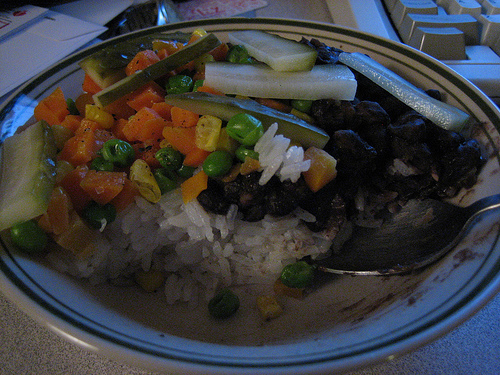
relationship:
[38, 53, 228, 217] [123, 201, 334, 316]
carrots on rice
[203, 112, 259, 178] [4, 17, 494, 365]
peas on dish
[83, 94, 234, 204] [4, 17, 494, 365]
corn on dish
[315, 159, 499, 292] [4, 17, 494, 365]
spoon on dish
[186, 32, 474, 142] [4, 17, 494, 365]
beans in dish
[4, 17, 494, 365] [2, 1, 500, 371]
dish on counter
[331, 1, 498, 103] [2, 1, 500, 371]
keyboard on counter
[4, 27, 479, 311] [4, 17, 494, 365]
food on dish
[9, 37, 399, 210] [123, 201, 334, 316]
vegetables on top of rice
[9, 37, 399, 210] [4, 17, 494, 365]
vegetables on dish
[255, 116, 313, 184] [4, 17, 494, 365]
rice on dish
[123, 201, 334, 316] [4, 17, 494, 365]
rice on dish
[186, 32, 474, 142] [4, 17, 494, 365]
beans on dish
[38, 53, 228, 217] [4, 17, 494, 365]
carrots on dish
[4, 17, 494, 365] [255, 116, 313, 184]
dish has rice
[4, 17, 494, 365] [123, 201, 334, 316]
dish has rice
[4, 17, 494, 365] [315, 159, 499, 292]
dish has spoon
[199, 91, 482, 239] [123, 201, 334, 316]
beans on top of rice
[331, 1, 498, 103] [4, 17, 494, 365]
keyboard next to dish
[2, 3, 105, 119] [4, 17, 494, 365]
letter next to dish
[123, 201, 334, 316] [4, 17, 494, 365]
rice at bottom of dish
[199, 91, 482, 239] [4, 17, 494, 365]
beans in dish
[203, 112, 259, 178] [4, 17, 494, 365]
peas in dish